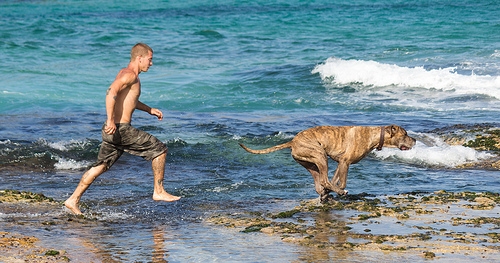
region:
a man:
[31, 11, 198, 233]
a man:
[80, 43, 252, 251]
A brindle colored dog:
[235, 117, 430, 207]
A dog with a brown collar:
[370, 113, 435, 163]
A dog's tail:
[233, 130, 290, 168]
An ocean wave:
[308, 40, 478, 117]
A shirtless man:
[99, 31, 166, 138]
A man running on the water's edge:
[68, 37, 193, 236]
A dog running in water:
[248, 108, 426, 210]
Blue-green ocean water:
[156, 3, 309, 103]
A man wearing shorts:
[79, 41, 191, 186]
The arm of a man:
[93, 69, 138, 139]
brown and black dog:
[240, 122, 419, 194]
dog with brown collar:
[236, 120, 414, 201]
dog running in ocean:
[247, 126, 411, 196]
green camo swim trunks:
[96, 122, 163, 169]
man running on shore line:
[70, 33, 187, 218]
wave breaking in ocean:
[301, 56, 499, 106]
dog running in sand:
[241, 123, 413, 196]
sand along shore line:
[3, 231, 75, 262]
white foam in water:
[392, 140, 497, 172]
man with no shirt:
[71, 46, 180, 222]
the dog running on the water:
[226, 112, 422, 204]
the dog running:
[230, 113, 424, 195]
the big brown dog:
[234, 117, 414, 194]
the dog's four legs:
[290, 153, 357, 198]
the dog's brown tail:
[230, 133, 290, 159]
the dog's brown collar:
[372, 121, 388, 152]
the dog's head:
[386, 122, 417, 152]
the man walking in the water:
[62, 35, 183, 215]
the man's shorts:
[82, 119, 167, 171]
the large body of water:
[4, 5, 497, 128]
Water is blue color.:
[21, 18, 301, 70]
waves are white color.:
[317, 46, 497, 108]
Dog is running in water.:
[281, 105, 406, 206]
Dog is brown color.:
[272, 120, 414, 197]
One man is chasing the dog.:
[56, 48, 191, 214]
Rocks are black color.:
[11, 140, 461, 259]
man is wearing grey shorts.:
[66, 108, 178, 179]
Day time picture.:
[18, 33, 475, 251]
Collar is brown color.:
[368, 114, 397, 162]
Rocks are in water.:
[11, 129, 466, 253]